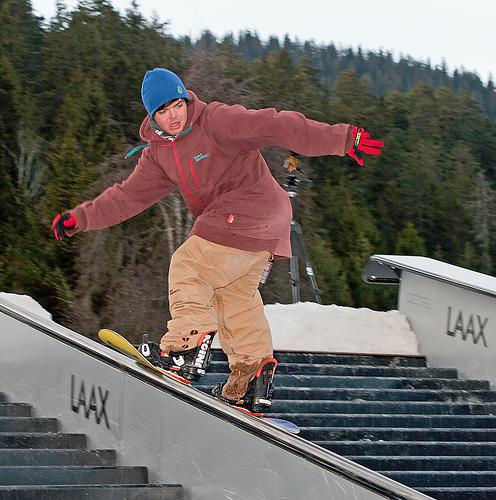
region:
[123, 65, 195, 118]
the cap is blue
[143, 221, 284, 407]
the pants are brown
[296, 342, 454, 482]
the stairs are gray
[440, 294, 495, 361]
the text is black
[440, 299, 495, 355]
the text reads laax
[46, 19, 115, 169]
the trees are green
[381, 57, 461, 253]
the trees are tall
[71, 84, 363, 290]
the jacket is red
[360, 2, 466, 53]
the sky is white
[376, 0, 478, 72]
the sky is clear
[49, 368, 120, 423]
laax is written on wall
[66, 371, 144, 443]
laax is written on wall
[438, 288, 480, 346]
laax is written on wall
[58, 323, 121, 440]
laax is written on wall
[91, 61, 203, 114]
the marvin is green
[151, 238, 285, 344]
the trousers are orange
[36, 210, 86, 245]
the gloves are orange and black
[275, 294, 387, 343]
there is snow on top of the stairs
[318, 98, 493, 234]
there are trees in the background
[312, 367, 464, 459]
the stair case is grey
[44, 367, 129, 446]
the woord laax is written on the wall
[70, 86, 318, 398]
he is balancing on the rail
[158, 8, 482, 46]
the sky is cloudless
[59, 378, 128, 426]
the word laax are in black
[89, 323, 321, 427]
A snowboard sliding down the rail.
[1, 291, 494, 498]
Two sets of black stairs.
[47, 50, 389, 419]
A man riding a snowboard.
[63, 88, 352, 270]
A red and brown coat worn by the man.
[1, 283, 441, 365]
Snow piled up at the top of the stairs.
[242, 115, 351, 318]
A camera on a tripod in the snow.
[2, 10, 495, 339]
A large forest on a hill.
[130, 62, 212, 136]
A blue cap worn by the man.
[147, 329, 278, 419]
A wet spot on the man's pants.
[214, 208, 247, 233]
A red tag for the coat.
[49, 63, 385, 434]
Boy in brown snowboarding a ledge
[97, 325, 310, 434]
snowboard under boy on a ledge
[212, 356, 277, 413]
black snowboarding boot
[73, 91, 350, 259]
brown coat on boy snowboarding a ledge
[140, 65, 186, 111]
blue wool cap on a boy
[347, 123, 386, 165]
red glove on a boy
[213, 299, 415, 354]
snow on top of stairs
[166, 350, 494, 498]
gray outdoor steps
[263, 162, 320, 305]
tripod behind snowboarder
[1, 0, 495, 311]
Green forest behind snowboarder